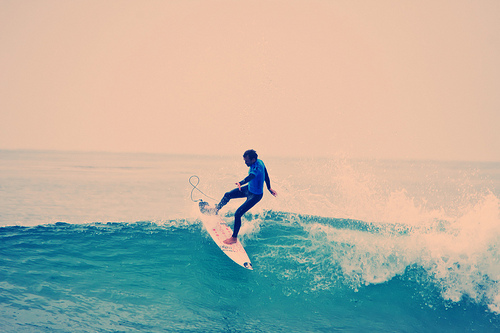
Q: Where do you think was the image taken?
A: It was taken at the ocean.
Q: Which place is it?
A: It is an ocean.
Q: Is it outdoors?
A: Yes, it is outdoors.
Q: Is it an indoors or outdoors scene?
A: It is outdoors.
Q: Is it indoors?
A: No, it is outdoors.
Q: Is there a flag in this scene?
A: No, there are no flags.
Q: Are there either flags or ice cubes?
A: No, there are no flags or ice cubes.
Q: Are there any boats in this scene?
A: No, there are no boats.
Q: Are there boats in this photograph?
A: No, there are no boats.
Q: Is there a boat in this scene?
A: No, there are no boats.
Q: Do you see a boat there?
A: No, there are no boats.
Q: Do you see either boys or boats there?
A: No, there are no boats or boys.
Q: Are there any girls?
A: No, there are no girls.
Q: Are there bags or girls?
A: No, there are no girls or bags.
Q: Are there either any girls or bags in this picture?
A: No, there are no girls or bags.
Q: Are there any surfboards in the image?
A: Yes, there is a surfboard.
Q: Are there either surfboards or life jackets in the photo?
A: Yes, there is a surfboard.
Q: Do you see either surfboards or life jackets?
A: Yes, there is a surfboard.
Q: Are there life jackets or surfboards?
A: Yes, there is a surfboard.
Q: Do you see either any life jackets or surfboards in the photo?
A: Yes, there is a surfboard.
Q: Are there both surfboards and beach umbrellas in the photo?
A: No, there is a surfboard but no beach umbrellas.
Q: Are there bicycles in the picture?
A: No, there are no bicycles.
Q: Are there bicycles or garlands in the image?
A: No, there are no bicycles or garlands.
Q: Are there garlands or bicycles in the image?
A: No, there are no bicycles or garlands.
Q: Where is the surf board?
A: The surf board is on the ocean.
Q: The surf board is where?
A: The surf board is on the ocean.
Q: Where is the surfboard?
A: The surf board is on the ocean.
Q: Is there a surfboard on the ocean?
A: Yes, there is a surfboard on the ocean.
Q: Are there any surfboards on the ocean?
A: Yes, there is a surfboard on the ocean.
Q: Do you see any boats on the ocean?
A: No, there is a surfboard on the ocean.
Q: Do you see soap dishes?
A: No, there are no soap dishes.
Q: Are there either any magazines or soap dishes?
A: No, there are no soap dishes or magazines.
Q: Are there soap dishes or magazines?
A: No, there are no soap dishes or magazines.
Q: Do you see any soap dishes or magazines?
A: No, there are no soap dishes or magazines.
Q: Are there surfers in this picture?
A: Yes, there is a surfer.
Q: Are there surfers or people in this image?
A: Yes, there is a surfer.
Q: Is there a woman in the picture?
A: No, there are no women.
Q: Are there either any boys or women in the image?
A: No, there are no women or boys.